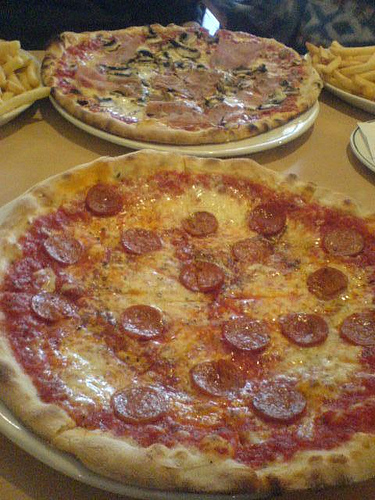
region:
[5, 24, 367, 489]
Two pizzas are on the table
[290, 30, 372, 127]
French Fries are on the table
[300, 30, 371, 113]
Fries are on a white plate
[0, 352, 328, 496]
Pizza is on a white plate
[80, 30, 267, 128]
Pizza has mushrooms as one of its toppings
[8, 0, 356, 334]
Photo was taken in the daytime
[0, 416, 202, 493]
White plate in the foreground is casting a shadow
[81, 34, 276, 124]
Pizza has ham as one of its toppings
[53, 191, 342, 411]
Pizza in the foreground topping is pepperoni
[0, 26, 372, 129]
Two fries are on the table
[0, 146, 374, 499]
large pepperoni pizza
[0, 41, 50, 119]
french fries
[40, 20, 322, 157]
sausage and mushrooms pizza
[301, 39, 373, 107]
delicious french fries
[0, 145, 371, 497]
great looking delicious pizza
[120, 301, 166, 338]
one pepperoni slice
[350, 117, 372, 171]
no food on the plate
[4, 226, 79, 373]
delicious tomato sauce makes pizza beautiful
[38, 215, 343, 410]
mozzarella cheese, pepperoni and tomato sauce make great pizza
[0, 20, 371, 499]
two pizzas and french fries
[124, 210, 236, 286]
pepperoni on a greasy pizza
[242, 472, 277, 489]
a burned edge on the pizza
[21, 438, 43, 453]
the edge of a white porcelain plate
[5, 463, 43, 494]
the shadow of the plate on the table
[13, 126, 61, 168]
a wooden table supporting the food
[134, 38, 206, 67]
mushrooms on top of a pizza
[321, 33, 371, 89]
a plate of french fries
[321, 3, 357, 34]
blue and white pattern on the shirt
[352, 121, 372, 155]
a white napkin on a plate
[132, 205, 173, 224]
melted cheese on the pizza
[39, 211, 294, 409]
pepporni on pizza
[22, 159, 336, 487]
a pepporoni pizza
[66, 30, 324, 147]
a mushroom pizza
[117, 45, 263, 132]
a pizza with mushrooms on it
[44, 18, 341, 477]
two pizzas on the table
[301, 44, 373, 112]
French fries plate on the right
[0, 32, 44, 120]
french fries on the plate to the left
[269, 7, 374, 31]
a really nice pattern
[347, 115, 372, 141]
a napkin on a plate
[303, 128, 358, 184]
a wooden table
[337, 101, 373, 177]
white plate with blue edging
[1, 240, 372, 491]
circular pepperoni pizza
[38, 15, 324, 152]
mushroom pizza on white plate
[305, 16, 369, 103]
french fries on white plate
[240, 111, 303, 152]
rounded edge of pizza with white plate showing through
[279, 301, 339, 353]
round piece of pepperoni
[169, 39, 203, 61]
blurry picture of mushroom on pizza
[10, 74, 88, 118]
one french fry touching piece of pizza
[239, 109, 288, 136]
burned spots of pizza crust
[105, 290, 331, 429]
six round pieces of pepperoni